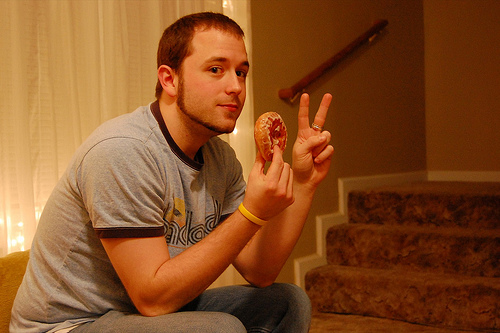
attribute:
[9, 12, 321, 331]
man — eating, married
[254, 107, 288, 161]
donut — frosted, brown, glazed, tasty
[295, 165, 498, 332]
stairs — brown, ascending, patterend, carpeted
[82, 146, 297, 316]
wristband — yellow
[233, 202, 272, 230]
wristband — yellow, rubber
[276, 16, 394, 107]
railing — wood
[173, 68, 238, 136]
facial hair — brown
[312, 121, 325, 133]
ring — silver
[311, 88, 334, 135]
finger — up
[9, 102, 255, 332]
t-shirt — light blue, grey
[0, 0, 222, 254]
curtains — white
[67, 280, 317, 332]
denim — light blue, grey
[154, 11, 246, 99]
hair — brown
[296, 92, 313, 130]
finger — up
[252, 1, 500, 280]
wall — yellow